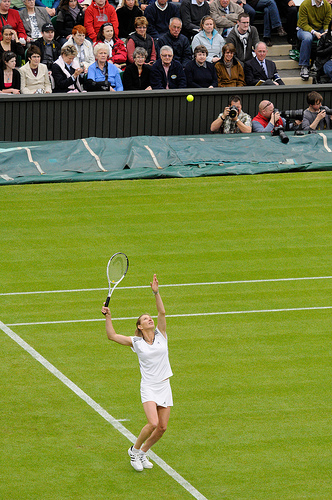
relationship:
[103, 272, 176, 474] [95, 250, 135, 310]
tennis player holding racket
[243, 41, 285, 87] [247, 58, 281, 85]
man wearing suit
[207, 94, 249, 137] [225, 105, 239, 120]
photographer holding camera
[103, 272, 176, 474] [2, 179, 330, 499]
tennis player playing on grass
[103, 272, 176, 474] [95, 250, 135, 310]
tennis player using racket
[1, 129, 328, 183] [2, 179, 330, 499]
tarp sitting on grass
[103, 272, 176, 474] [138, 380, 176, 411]
tennis player wearing skirt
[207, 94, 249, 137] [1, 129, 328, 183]
photographer near tarp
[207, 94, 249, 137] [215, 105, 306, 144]
photographer with cameras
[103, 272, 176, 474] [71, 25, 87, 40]
tennis player with hair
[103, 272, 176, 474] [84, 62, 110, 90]
tennis player with arm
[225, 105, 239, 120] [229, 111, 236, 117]
camera with lens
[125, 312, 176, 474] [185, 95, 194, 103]
tennis player throwing ball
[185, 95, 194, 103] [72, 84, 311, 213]
ball in air